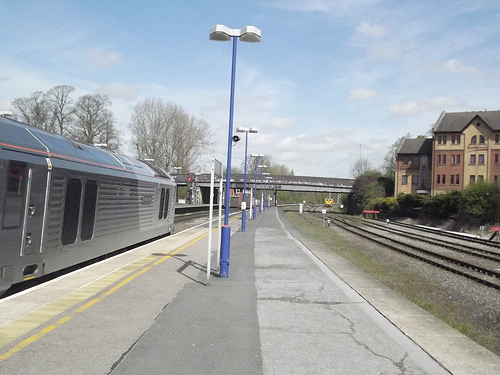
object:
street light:
[209, 24, 262, 277]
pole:
[219, 37, 238, 277]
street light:
[235, 126, 259, 232]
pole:
[241, 132, 248, 232]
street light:
[249, 153, 266, 219]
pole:
[252, 158, 258, 219]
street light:
[256, 164, 269, 217]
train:
[0, 115, 177, 298]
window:
[61, 178, 83, 246]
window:
[80, 179, 100, 240]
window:
[158, 187, 166, 220]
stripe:
[0, 142, 155, 176]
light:
[209, 32, 230, 41]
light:
[238, 32, 261, 42]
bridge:
[173, 172, 357, 205]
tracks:
[306, 205, 499, 291]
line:
[0, 217, 217, 367]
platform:
[1, 204, 454, 374]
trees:
[251, 156, 294, 176]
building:
[431, 108, 499, 196]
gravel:
[394, 260, 422, 303]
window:
[163, 187, 170, 219]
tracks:
[174, 199, 242, 231]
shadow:
[150, 252, 222, 287]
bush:
[453, 183, 500, 225]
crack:
[318, 304, 411, 373]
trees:
[128, 97, 218, 174]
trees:
[10, 84, 79, 135]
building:
[393, 134, 432, 195]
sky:
[0, 1, 500, 178]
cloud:
[380, 95, 462, 117]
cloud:
[68, 44, 120, 67]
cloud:
[354, 21, 392, 41]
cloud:
[277, 134, 355, 156]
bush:
[419, 188, 461, 223]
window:
[477, 153, 485, 165]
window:
[469, 154, 476, 166]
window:
[454, 174, 460, 184]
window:
[479, 134, 485, 145]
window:
[435, 153, 440, 165]